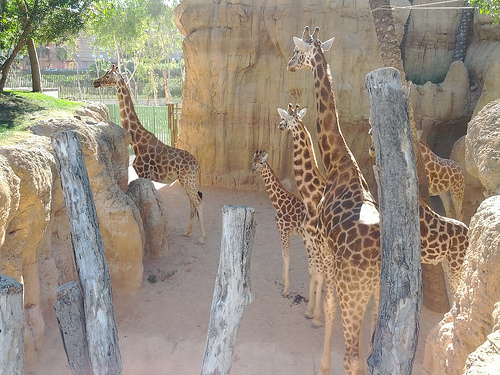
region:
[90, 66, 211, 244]
a giraffe in a stone enclosure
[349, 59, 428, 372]
a tall wooden stick at a zoo.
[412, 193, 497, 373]
a rock wall in an enclosure.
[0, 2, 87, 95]
a tree with lots of leaves.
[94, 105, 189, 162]
a fence near a giraffe enclosure.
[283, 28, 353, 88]
the head of a tall giraffe.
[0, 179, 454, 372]
the ground in a giraffe exhibit.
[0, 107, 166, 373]
a rock wall near giraffe.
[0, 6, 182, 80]
buildings near a park.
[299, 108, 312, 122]
the right of a giraffe.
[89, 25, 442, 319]
group of giraffes standing in shade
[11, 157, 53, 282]
large brown cliff face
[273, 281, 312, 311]
black giraffe droppings on ground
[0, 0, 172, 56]
trees with green leaves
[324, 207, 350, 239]
pattern on side of giraffe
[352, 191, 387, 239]
sun shining on back of giraffe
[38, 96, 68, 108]
green grass growing on top of cliff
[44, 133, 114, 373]
grey wooden logs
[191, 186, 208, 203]
black fur on tail of giraffe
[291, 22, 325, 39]
small horns on giraffe head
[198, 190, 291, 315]
a wood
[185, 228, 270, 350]
a wood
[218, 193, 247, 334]
a wood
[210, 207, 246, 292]
a wood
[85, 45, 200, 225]
brown and beige giraffe next to rocks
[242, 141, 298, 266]
small giraffe next to giraffe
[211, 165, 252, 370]
small tree trunk in sand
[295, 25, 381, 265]
tall giraffe next to rocks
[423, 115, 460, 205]
small giraffe next to rocks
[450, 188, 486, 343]
rocks next to tree trunk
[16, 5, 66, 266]
leaves on a tall tree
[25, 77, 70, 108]
grass near rocks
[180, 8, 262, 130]
large rock wall next to fence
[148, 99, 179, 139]
fence next to rock wall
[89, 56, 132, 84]
a head of a horned giraffe.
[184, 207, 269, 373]
a dried up old piece of wood.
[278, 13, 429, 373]
a tall giraffe in an enclosure.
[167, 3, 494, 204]
a stone wall near giraffe.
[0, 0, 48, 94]
a tall leafy tree.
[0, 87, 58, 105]
A planter in a park.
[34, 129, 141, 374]
a log in a cage.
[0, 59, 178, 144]
a lush green park.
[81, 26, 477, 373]
a herd of giraffe.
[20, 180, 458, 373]
a rock ground.